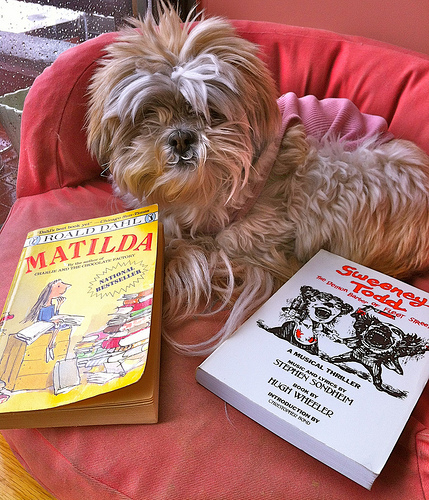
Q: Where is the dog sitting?
A: On a chair.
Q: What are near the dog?
A: Books.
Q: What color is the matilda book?
A: Yellow.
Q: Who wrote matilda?
A: Roald Dahl.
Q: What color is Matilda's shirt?
A: Blue.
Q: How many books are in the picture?
A: Two.